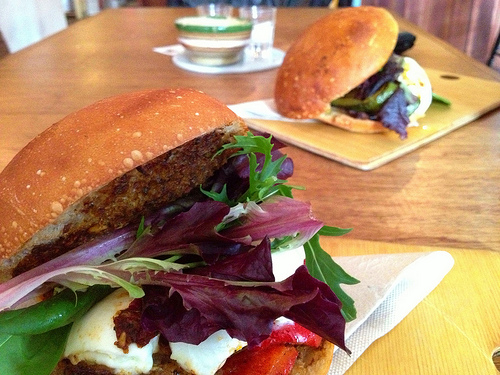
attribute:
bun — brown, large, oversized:
[274, 6, 401, 119]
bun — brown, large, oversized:
[0, 86, 253, 282]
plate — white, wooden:
[232, 66, 500, 167]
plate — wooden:
[316, 236, 498, 373]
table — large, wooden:
[3, 8, 499, 255]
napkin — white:
[219, 96, 317, 122]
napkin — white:
[317, 251, 456, 374]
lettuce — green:
[2, 277, 115, 373]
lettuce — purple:
[115, 199, 347, 351]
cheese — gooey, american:
[63, 249, 307, 373]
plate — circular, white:
[173, 41, 288, 75]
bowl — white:
[174, 16, 251, 68]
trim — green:
[174, 15, 253, 34]